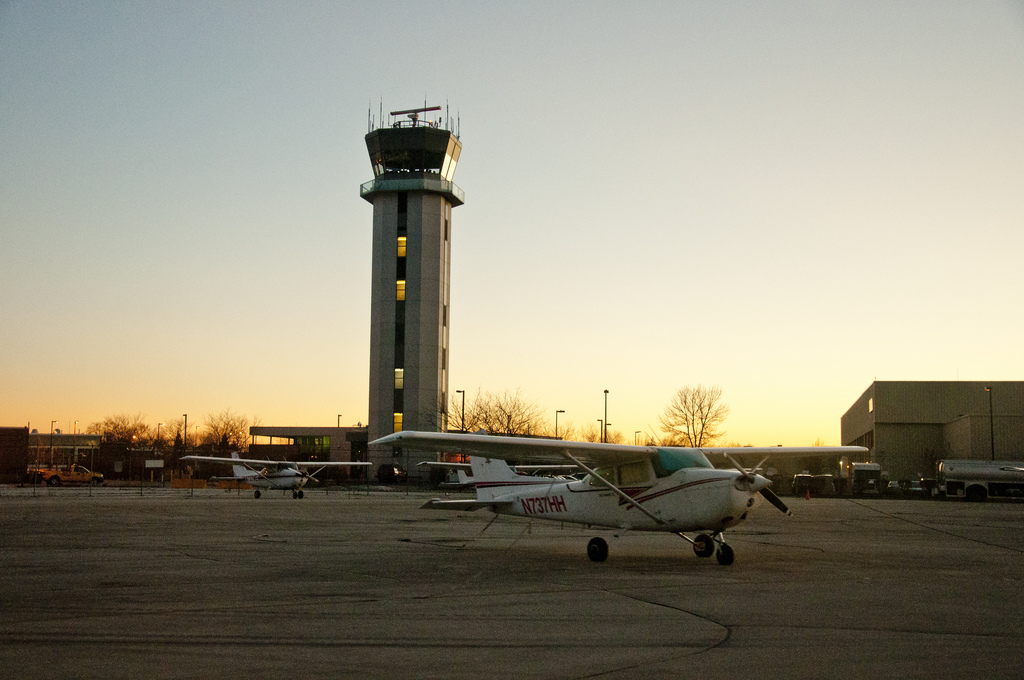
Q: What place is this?
A: It is a city.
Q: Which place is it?
A: It is a city.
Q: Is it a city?
A: Yes, it is a city.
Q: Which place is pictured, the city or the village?
A: It is the city.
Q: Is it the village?
A: No, it is the city.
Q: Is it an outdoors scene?
A: Yes, it is outdoors.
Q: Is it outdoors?
A: Yes, it is outdoors.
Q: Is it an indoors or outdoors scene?
A: It is outdoors.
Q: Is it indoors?
A: No, it is outdoors.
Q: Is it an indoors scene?
A: No, it is outdoors.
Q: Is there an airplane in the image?
A: Yes, there is an airplane.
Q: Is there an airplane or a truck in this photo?
A: Yes, there is an airplane.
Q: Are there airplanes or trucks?
A: Yes, there is an airplane.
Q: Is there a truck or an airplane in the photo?
A: Yes, there is an airplane.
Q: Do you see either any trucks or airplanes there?
A: Yes, there is an airplane.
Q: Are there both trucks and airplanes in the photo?
A: Yes, there are both an airplane and a truck.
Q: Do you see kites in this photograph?
A: No, there are no kites.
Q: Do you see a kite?
A: No, there are no kites.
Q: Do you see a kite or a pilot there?
A: No, there are no kites or pilots.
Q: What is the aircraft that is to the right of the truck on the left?
A: The aircraft is an airplane.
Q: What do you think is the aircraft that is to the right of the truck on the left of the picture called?
A: The aircraft is an airplane.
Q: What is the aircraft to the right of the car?
A: The aircraft is an airplane.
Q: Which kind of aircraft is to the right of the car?
A: The aircraft is an airplane.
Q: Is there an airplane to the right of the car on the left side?
A: Yes, there is an airplane to the right of the car.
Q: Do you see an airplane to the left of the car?
A: No, the airplane is to the right of the car.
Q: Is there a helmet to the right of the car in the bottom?
A: No, there is an airplane to the right of the car.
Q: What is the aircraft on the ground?
A: The aircraft is an airplane.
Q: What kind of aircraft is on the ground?
A: The aircraft is an airplane.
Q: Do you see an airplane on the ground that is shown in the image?
A: Yes, there is an airplane on the ground.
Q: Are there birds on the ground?
A: No, there is an airplane on the ground.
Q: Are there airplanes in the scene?
A: Yes, there are airplanes.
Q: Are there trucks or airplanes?
A: Yes, there are airplanes.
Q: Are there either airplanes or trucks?
A: Yes, there are airplanes.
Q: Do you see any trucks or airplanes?
A: Yes, there are airplanes.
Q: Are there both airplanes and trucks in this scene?
A: Yes, there are both airplanes and a truck.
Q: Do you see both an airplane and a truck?
A: Yes, there are both an airplane and a truck.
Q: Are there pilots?
A: No, there are no pilots.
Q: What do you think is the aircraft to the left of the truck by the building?
A: The aircraft is airplanes.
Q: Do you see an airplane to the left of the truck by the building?
A: Yes, there are airplanes to the left of the truck.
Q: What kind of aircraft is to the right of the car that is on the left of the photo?
A: The aircraft is airplanes.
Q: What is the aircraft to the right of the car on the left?
A: The aircraft is airplanes.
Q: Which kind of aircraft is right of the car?
A: The aircraft is airplanes.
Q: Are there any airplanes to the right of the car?
A: Yes, there are airplanes to the right of the car.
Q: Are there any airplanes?
A: Yes, there is an airplane.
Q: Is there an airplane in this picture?
A: Yes, there is an airplane.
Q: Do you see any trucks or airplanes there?
A: Yes, there is an airplane.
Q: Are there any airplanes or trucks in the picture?
A: Yes, there is an airplane.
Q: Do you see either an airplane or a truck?
A: Yes, there is an airplane.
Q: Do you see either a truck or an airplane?
A: Yes, there is an airplane.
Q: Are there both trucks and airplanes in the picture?
A: Yes, there are both an airplane and a truck.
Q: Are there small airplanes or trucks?
A: Yes, there is a small airplane.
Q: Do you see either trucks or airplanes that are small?
A: Yes, the airplane is small.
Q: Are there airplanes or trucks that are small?
A: Yes, the airplane is small.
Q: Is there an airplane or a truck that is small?
A: Yes, the airplane is small.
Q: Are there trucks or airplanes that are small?
A: Yes, the airplane is small.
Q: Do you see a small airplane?
A: Yes, there is a small airplane.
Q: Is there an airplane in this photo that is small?
A: Yes, there is an airplane that is small.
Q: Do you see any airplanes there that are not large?
A: Yes, there is a small airplane.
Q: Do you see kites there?
A: No, there are no kites.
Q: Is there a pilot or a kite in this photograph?
A: No, there are no kites or pilots.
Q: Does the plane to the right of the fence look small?
A: Yes, the airplane is small.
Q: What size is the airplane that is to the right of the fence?
A: The plane is small.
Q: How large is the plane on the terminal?
A: The airplane is small.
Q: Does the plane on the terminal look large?
A: No, the airplane is small.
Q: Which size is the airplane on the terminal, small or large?
A: The airplane is small.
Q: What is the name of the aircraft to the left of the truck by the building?
A: The aircraft is an airplane.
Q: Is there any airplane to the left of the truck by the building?
A: Yes, there is an airplane to the left of the truck.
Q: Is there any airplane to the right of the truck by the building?
A: No, the airplane is to the left of the truck.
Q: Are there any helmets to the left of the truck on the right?
A: No, there is an airplane to the left of the truck.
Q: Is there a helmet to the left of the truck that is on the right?
A: No, there is an airplane to the left of the truck.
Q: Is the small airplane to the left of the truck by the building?
A: Yes, the airplane is to the left of the truck.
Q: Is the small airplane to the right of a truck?
A: No, the airplane is to the left of a truck.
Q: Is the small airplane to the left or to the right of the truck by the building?
A: The airplane is to the left of the truck.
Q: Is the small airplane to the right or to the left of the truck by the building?
A: The airplane is to the left of the truck.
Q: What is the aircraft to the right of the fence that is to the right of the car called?
A: The aircraft is an airplane.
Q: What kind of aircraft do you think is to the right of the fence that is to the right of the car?
A: The aircraft is an airplane.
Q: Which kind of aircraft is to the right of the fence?
A: The aircraft is an airplane.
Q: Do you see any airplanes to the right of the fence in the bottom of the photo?
A: Yes, there is an airplane to the right of the fence.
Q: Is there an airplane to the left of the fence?
A: No, the airplane is to the right of the fence.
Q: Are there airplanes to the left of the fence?
A: No, the airplane is to the right of the fence.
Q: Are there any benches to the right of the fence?
A: No, there is an airplane to the right of the fence.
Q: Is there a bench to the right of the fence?
A: No, there is an airplane to the right of the fence.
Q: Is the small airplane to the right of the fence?
A: Yes, the airplane is to the right of the fence.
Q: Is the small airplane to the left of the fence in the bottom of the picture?
A: No, the airplane is to the right of the fence.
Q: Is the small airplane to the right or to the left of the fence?
A: The airplane is to the right of the fence.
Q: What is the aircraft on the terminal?
A: The aircraft is an airplane.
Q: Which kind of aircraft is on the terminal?
A: The aircraft is an airplane.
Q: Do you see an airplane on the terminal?
A: Yes, there is an airplane on the terminal.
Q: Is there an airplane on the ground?
A: Yes, there is an airplane on the ground.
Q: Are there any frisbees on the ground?
A: No, there is an airplane on the ground.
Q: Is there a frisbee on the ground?
A: No, there is an airplane on the ground.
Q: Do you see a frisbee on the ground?
A: No, there is an airplane on the ground.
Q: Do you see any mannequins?
A: No, there are no mannequins.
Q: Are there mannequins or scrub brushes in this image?
A: No, there are no mannequins or scrub brushes.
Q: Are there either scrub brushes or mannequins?
A: No, there are no mannequins or scrub brushes.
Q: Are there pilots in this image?
A: No, there are no pilots.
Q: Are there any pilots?
A: No, there are no pilots.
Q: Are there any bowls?
A: No, there are no bowls.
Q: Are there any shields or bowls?
A: No, there are no bowls or shields.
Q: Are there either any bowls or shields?
A: No, there are no bowls or shields.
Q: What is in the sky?
A: The clouds are in the sky.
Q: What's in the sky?
A: The clouds are in the sky.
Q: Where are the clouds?
A: The clouds are in the sky.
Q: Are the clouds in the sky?
A: Yes, the clouds are in the sky.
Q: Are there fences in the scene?
A: Yes, there is a fence.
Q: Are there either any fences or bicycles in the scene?
A: Yes, there is a fence.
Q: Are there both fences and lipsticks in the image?
A: No, there is a fence but no lipsticks.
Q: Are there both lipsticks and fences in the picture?
A: No, there is a fence but no lipsticks.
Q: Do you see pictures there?
A: No, there are no pictures.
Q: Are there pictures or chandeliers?
A: No, there are no pictures or chandeliers.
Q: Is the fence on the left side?
A: Yes, the fence is on the left of the image.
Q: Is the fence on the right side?
A: No, the fence is on the left of the image.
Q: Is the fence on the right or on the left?
A: The fence is on the left of the image.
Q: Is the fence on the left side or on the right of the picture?
A: The fence is on the left of the image.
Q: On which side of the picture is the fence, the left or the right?
A: The fence is on the left of the image.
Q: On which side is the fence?
A: The fence is on the left of the image.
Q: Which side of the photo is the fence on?
A: The fence is on the left of the image.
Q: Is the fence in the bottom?
A: Yes, the fence is in the bottom of the image.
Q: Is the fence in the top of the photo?
A: No, the fence is in the bottom of the image.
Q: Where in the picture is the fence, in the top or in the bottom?
A: The fence is in the bottom of the image.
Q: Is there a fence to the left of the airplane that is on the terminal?
A: Yes, there is a fence to the left of the airplane.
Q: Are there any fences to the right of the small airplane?
A: No, the fence is to the left of the plane.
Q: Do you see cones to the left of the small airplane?
A: No, there is a fence to the left of the plane.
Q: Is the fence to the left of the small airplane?
A: Yes, the fence is to the left of the airplane.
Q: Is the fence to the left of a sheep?
A: No, the fence is to the left of the airplane.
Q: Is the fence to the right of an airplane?
A: No, the fence is to the left of an airplane.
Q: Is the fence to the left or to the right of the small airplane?
A: The fence is to the left of the airplane.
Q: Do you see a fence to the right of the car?
A: Yes, there is a fence to the right of the car.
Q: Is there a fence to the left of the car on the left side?
A: No, the fence is to the right of the car.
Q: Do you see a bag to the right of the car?
A: No, there is a fence to the right of the car.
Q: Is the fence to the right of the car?
A: Yes, the fence is to the right of the car.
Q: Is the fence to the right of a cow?
A: No, the fence is to the right of the car.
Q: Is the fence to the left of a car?
A: No, the fence is to the right of a car.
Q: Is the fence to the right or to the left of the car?
A: The fence is to the right of the car.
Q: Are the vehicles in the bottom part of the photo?
A: Yes, the vehicles are in the bottom of the image.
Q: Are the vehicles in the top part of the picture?
A: No, the vehicles are in the bottom of the image.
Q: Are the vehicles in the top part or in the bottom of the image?
A: The vehicles are in the bottom of the image.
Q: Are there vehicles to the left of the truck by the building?
A: Yes, there are vehicles to the left of the truck.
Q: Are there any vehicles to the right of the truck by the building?
A: No, the vehicles are to the left of the truck.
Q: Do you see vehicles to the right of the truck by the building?
A: No, the vehicles are to the left of the truck.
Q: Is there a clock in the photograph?
A: No, there are no clocks.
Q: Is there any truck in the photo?
A: Yes, there is a truck.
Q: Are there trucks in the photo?
A: Yes, there is a truck.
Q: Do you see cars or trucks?
A: Yes, there is a truck.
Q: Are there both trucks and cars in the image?
A: Yes, there are both a truck and a car.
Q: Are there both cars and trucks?
A: Yes, there are both a truck and a car.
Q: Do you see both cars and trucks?
A: Yes, there are both a truck and a car.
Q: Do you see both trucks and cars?
A: Yes, there are both a truck and a car.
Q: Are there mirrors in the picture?
A: No, there are no mirrors.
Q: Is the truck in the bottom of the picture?
A: Yes, the truck is in the bottom of the image.